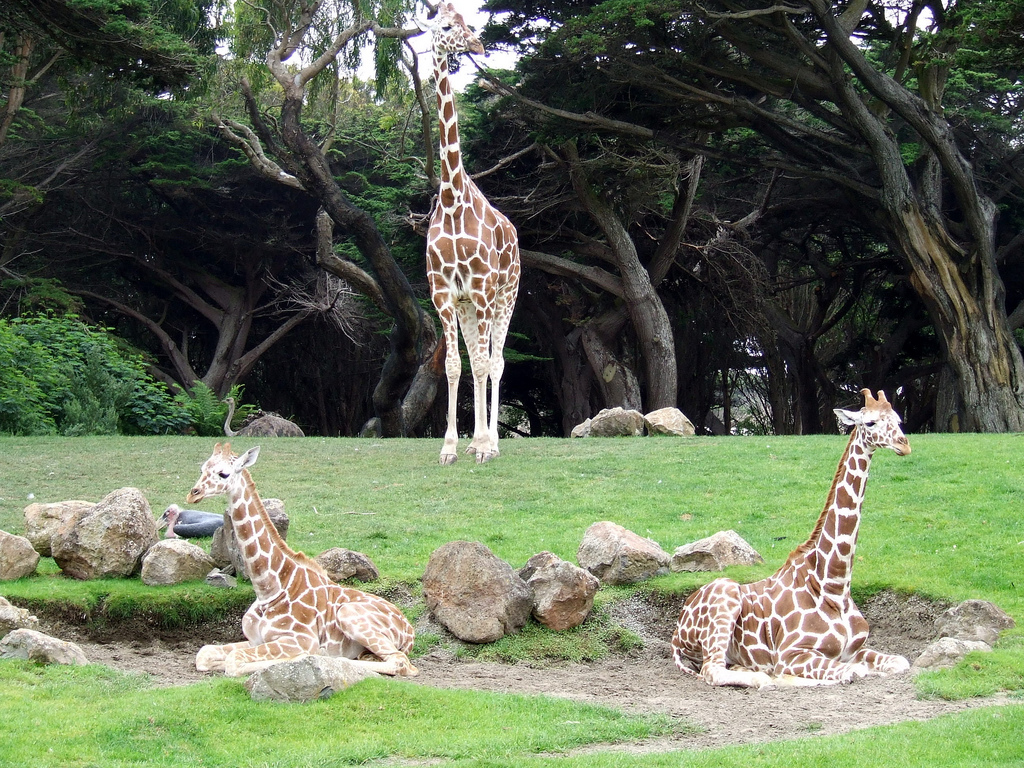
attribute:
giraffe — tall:
[417, 13, 530, 482]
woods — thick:
[0, 0, 1022, 435]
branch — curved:
[570, 173, 689, 415]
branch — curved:
[810, 5, 1005, 317]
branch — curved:
[86, 5, 411, 440]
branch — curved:
[648, 117, 709, 278]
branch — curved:
[464, 74, 681, 155]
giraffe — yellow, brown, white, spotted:
[181, 435, 421, 693]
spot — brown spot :
[464, 217, 480, 233]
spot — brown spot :
[464, 219, 484, 252]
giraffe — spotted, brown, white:
[664, 379, 913, 689]